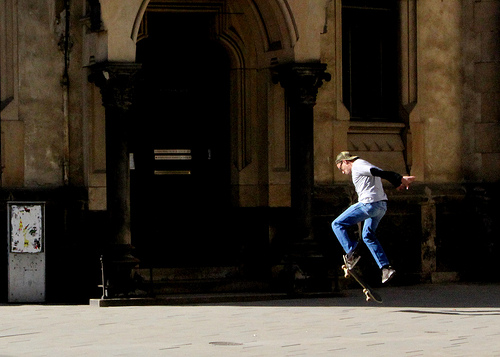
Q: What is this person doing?
A: Riding a skateboard.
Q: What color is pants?
A: Blue.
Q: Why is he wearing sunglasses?
A: It is sunny.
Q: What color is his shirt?
A: Grey.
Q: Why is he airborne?
A: He jumped.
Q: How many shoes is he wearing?
A: Two.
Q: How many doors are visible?
A: One.